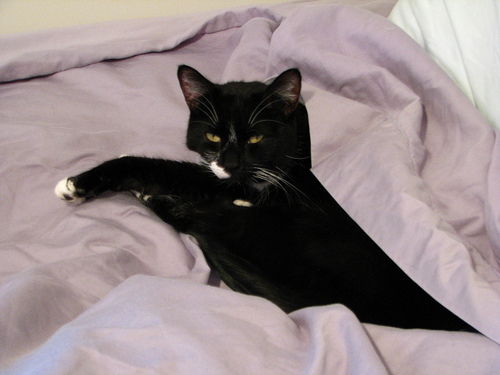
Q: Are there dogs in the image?
A: No, there are no dogs.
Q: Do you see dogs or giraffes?
A: No, there are no dogs or giraffes.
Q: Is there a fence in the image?
A: No, there are no fences.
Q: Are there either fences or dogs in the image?
A: No, there are no fences or dogs.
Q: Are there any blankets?
A: Yes, there is a blanket.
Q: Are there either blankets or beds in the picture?
A: Yes, there is a blanket.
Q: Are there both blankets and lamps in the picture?
A: No, there is a blanket but no lamps.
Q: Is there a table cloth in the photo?
A: No, there are no tablecloths.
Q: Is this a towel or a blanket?
A: This is a blanket.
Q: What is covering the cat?
A: The blanket is covering the cat.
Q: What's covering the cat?
A: The blanket is covering the cat.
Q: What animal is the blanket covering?
A: The blanket is covering the cat.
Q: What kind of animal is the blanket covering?
A: The blanket is covering the cat.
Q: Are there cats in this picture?
A: Yes, there is a cat.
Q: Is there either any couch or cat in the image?
A: Yes, there is a cat.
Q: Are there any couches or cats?
A: Yes, there is a cat.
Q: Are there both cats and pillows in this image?
A: Yes, there are both a cat and a pillow.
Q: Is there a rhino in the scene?
A: No, there are no rhinos.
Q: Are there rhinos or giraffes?
A: No, there are no rhinos or giraffes.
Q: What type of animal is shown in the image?
A: The animal is a cat.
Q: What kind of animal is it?
A: The animal is a cat.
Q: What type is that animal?
A: This is a cat.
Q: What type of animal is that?
A: This is a cat.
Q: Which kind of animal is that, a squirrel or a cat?
A: This is a cat.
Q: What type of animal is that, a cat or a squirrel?
A: This is a cat.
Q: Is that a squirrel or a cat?
A: That is a cat.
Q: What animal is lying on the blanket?
A: The cat is lying on the blanket.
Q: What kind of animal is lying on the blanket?
A: The animal is a cat.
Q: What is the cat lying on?
A: The cat is lying on the blanket.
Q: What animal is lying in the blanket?
A: The cat is lying in the blanket.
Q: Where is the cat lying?
A: The cat is lying in the blanket.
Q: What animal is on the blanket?
A: The cat is on the blanket.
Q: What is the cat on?
A: The cat is on the blanket.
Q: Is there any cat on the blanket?
A: Yes, there is a cat on the blanket.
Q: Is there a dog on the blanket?
A: No, there is a cat on the blanket.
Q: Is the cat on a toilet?
A: No, the cat is on the blanket.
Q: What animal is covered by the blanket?
A: The cat is covered by the blanket.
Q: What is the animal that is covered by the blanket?
A: The animal is a cat.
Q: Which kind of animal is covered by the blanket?
A: The animal is a cat.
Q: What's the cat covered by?
A: The cat is covered by the blanket.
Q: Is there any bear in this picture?
A: No, there are no bears.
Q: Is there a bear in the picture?
A: No, there are no bears.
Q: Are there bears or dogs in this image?
A: No, there are no bears or dogs.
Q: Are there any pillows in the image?
A: Yes, there is a pillow.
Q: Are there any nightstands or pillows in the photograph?
A: Yes, there is a pillow.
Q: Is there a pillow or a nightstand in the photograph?
A: Yes, there is a pillow.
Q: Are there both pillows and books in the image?
A: No, there is a pillow but no books.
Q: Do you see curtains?
A: No, there are no curtains.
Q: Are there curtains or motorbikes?
A: No, there are no curtains or motorbikes.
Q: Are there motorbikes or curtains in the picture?
A: No, there are no curtains or motorbikes.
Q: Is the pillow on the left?
A: No, the pillow is on the right of the image.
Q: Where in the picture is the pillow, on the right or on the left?
A: The pillow is on the right of the image.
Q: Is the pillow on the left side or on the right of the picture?
A: The pillow is on the right of the image.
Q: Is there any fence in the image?
A: No, there are no fences.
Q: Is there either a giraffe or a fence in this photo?
A: No, there are no fences or giraffes.